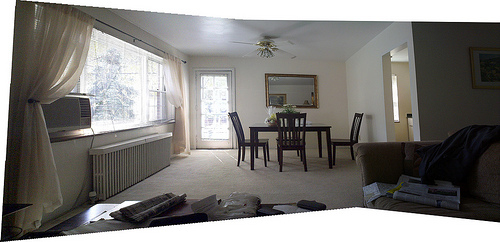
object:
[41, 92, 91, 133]
air conditioner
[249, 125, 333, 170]
table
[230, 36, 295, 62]
fan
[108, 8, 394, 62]
ceiling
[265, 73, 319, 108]
mirror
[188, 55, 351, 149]
wall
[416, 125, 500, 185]
blanket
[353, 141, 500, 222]
couch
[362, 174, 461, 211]
papers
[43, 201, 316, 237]
table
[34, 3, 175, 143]
window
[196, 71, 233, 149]
door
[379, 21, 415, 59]
archway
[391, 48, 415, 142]
another room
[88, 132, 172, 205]
heater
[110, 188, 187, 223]
newspaper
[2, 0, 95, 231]
curtains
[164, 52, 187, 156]
curtains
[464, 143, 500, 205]
back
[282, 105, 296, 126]
flowers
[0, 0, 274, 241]
left side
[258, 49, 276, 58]
lights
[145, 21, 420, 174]
dining room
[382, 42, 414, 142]
passageway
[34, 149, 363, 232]
floor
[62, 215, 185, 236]
magazine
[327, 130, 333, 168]
stand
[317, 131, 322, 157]
stand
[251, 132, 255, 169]
stand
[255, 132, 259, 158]
stand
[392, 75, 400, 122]
window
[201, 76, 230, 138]
window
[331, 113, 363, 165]
chair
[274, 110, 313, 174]
chair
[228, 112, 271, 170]
chair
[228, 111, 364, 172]
dining set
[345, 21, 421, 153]
wall